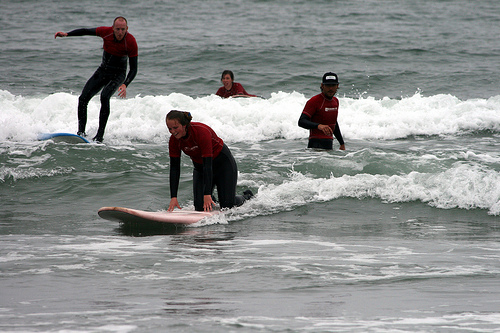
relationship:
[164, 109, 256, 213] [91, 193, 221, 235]
lady on surfboard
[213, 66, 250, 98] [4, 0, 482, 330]
woman in water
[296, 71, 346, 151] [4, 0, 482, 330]
man standing in water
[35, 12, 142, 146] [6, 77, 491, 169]
man surfing on a wave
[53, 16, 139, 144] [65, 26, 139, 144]
man wearing surf suit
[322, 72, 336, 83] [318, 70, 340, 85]
design on hat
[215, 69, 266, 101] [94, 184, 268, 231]
woman laying on surfboard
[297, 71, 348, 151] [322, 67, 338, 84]
man wearing hat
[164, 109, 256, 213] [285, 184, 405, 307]
lady in shallows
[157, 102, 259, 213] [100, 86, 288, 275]
lady learning to surf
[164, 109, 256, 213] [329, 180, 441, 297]
lady in ocean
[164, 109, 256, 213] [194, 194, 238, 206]
lady on her knees